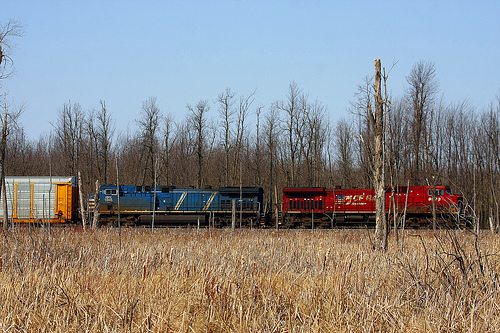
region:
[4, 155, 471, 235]
This is a train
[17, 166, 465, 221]
The train has three cars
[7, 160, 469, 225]
All of the train cars are different colors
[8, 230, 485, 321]
Brown brush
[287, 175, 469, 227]
This is the driver's train car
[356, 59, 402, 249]
A narrow tree trunk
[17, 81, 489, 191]
A bunch of brown trees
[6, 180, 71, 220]
Silver doors on the yellow car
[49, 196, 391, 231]
A fence next to the train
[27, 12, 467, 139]
Blue sky behind the trees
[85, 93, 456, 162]
trees with no leaves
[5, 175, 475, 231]
three train cars on railroad tracks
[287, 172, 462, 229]
red train car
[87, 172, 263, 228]
blue train car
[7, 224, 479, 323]
large field of tall dead grass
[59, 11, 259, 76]
bright blue clear sky with no clouds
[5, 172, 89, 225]
silver and yellow train car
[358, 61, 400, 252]
dead tree in the field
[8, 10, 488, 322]
photograph of train going through woody area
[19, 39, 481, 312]
photograph taken during the winter months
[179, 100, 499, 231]
a train on train tracks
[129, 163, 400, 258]
a train on train tracks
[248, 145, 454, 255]
a train on train tracks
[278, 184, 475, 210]
red engine in the front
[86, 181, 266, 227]
second car is blue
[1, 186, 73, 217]
yellow car carrying white items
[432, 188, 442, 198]
engineer in front of car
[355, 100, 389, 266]
tall tree in front of train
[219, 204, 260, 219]
black rail on blue car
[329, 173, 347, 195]
smoke stack on red car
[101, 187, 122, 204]
two windows on back of car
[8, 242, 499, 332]
grass alongside tracks are brown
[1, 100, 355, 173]
trees in distance are bare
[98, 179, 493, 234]
red and blue locomotives on train tracks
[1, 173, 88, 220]
yellow train car on the tracks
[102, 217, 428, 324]
grass growing near the train tracks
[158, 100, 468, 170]
trees without any leaves on them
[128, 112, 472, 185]
Trees near the train tracks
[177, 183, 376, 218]
red and blue locomotives on train tracks